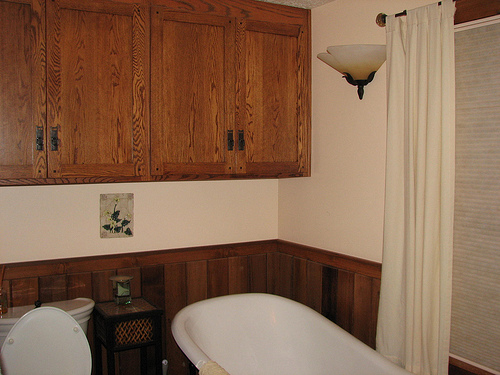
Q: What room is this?
A: Toilet.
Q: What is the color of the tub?
A: White.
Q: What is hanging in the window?
A: Screen.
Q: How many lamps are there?
A: One.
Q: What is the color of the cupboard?
A: Brown.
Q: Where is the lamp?
A: In the wall.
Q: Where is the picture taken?
A: Bathroom.